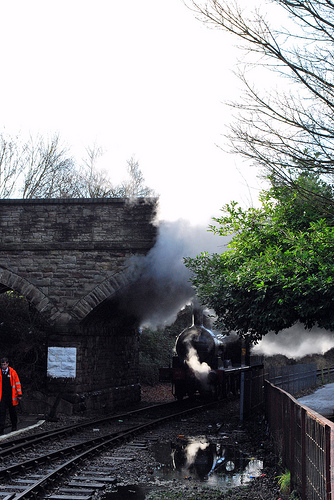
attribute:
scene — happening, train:
[34, 121, 286, 372]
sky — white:
[96, 21, 165, 137]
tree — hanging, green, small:
[225, 31, 332, 132]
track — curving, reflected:
[30, 375, 188, 452]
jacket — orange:
[3, 352, 44, 421]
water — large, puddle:
[293, 384, 327, 429]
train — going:
[156, 268, 280, 410]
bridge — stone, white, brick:
[0, 150, 190, 303]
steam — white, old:
[257, 280, 318, 370]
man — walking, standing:
[2, 351, 24, 416]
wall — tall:
[42, 231, 105, 326]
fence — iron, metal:
[181, 367, 306, 494]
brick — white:
[50, 274, 116, 324]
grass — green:
[272, 453, 309, 489]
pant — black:
[0, 392, 29, 431]